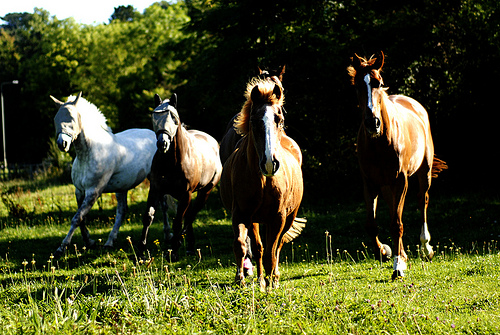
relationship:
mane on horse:
[231, 73, 285, 137] [220, 63, 304, 291]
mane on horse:
[347, 52, 376, 85] [345, 48, 447, 280]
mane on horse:
[65, 94, 112, 135] [49, 92, 159, 251]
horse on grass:
[45, 91, 159, 256] [2, 162, 500, 334]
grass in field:
[2, 162, 500, 334] [0, 2, 499, 333]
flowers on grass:
[22, 233, 499, 321] [2, 162, 500, 334]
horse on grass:
[49, 92, 159, 251] [2, 162, 500, 334]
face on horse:
[250, 104, 281, 176] [220, 63, 304, 291]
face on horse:
[153, 105, 175, 152] [142, 89, 223, 257]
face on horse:
[355, 68, 386, 136] [345, 48, 447, 280]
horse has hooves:
[220, 63, 304, 291] [238, 267, 278, 287]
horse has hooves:
[49, 92, 159, 251] [56, 229, 173, 255]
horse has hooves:
[345, 48, 447, 280] [382, 243, 436, 280]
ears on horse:
[251, 85, 281, 99] [220, 63, 304, 291]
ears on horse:
[352, 51, 384, 69] [345, 48, 447, 280]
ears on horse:
[48, 92, 82, 105] [49, 92, 159, 251]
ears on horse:
[153, 94, 178, 106] [142, 89, 223, 257]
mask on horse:
[150, 108, 177, 141] [142, 89, 223, 257]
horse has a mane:
[49, 92, 159, 251] [65, 94, 112, 135]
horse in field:
[45, 91, 159, 256] [0, 2, 499, 333]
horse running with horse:
[49, 92, 159, 251] [345, 48, 447, 283]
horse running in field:
[345, 48, 447, 283] [0, 2, 499, 333]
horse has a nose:
[220, 63, 304, 291] [258, 155, 280, 179]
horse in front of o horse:
[220, 63, 304, 291] [142, 89, 223, 257]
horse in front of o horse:
[220, 63, 304, 291] [49, 92, 159, 251]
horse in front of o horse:
[220, 63, 304, 291] [345, 48, 447, 280]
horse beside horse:
[142, 89, 223, 257] [49, 92, 159, 251]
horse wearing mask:
[45, 91, 159, 256] [50, 105, 83, 138]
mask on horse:
[52, 105, 83, 138] [49, 92, 159, 251]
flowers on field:
[22, 233, 499, 321] [0, 2, 499, 333]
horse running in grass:
[45, 91, 159, 256] [2, 162, 500, 334]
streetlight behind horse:
[2, 79, 19, 179] [45, 91, 159, 256]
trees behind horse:
[1, 0, 499, 208] [45, 91, 159, 256]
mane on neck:
[231, 73, 285, 137] [245, 111, 261, 164]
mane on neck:
[347, 52, 376, 85] [380, 85, 393, 138]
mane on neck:
[65, 94, 112, 135] [73, 117, 104, 152]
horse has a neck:
[220, 63, 304, 291] [245, 111, 261, 164]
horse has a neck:
[345, 48, 447, 280] [380, 85, 393, 138]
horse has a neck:
[49, 92, 159, 251] [73, 117, 104, 152]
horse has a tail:
[220, 63, 304, 291] [283, 212, 308, 245]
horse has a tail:
[345, 48, 447, 280] [433, 157, 448, 181]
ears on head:
[251, 85, 281, 99] [248, 83, 283, 176]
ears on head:
[352, 51, 384, 69] [349, 50, 385, 138]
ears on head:
[48, 92, 82, 105] [50, 90, 85, 151]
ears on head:
[153, 94, 178, 106] [151, 92, 179, 155]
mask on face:
[150, 108, 177, 141] [153, 105, 175, 152]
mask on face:
[52, 105, 83, 138] [54, 107, 73, 145]